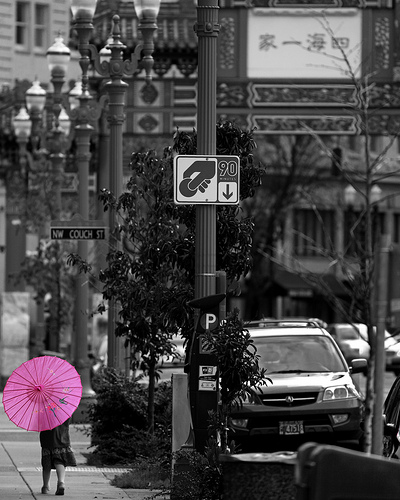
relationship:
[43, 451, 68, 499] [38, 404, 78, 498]
leg of girl